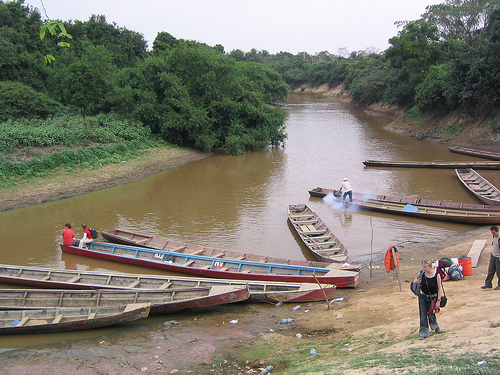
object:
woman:
[413, 259, 444, 340]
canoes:
[0, 263, 337, 302]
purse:
[434, 295, 450, 308]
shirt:
[61, 228, 75, 246]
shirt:
[341, 180, 352, 192]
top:
[418, 271, 440, 296]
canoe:
[59, 238, 359, 288]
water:
[228, 101, 411, 229]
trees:
[189, 72, 287, 156]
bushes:
[22, 127, 147, 173]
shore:
[61, 139, 202, 189]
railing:
[98, 241, 328, 272]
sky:
[191, 2, 384, 35]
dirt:
[64, 164, 166, 190]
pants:
[418, 293, 439, 338]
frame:
[94, 244, 138, 259]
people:
[60, 222, 94, 250]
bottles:
[275, 301, 301, 323]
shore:
[150, 301, 369, 357]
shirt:
[83, 226, 94, 241]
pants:
[78, 237, 95, 249]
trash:
[164, 302, 317, 374]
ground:
[198, 226, 499, 374]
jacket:
[384, 245, 401, 273]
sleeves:
[436, 273, 443, 304]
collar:
[423, 274, 437, 279]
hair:
[422, 259, 439, 270]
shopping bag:
[401, 204, 419, 212]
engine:
[333, 189, 343, 197]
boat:
[308, 185, 499, 224]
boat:
[455, 168, 499, 205]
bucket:
[458, 256, 472, 276]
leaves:
[39, 12, 71, 64]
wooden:
[466, 240, 487, 268]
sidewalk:
[465, 238, 487, 268]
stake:
[369, 217, 374, 277]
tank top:
[421, 273, 438, 294]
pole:
[392, 247, 403, 292]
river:
[298, 91, 386, 174]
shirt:
[490, 233, 500, 257]